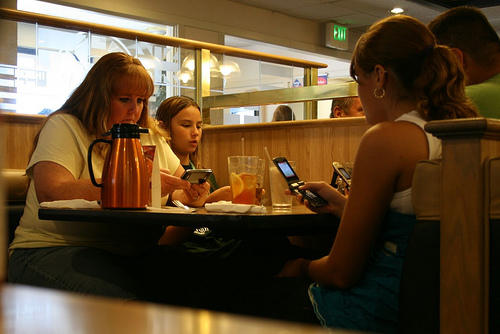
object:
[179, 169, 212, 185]
cell phone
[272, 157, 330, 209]
cell phone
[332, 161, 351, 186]
cell phone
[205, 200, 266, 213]
napkin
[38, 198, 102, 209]
napkin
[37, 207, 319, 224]
edge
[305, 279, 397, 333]
jeans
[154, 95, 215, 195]
hair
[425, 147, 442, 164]
ground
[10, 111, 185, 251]
shirt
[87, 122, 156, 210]
coffee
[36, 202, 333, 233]
table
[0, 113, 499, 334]
restaurant booth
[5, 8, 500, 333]
four people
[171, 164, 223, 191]
cell phone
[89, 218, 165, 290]
tip table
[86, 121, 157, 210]
pot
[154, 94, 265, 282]
person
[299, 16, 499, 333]
person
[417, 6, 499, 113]
person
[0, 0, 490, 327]
booth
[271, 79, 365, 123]
patrons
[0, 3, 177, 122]
window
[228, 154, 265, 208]
glass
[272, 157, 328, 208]
phone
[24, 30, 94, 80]
glass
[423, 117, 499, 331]
chair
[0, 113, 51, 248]
chair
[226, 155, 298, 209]
cups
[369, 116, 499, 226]
shoulder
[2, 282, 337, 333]
surface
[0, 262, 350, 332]
table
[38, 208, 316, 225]
table edge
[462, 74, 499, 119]
shirt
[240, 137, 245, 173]
straw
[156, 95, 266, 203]
girl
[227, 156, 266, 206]
cup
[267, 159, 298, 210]
cup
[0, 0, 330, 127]
divider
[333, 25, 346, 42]
lettering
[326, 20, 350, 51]
sign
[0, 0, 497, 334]
restaurant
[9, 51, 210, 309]
mom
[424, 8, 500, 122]
male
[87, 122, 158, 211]
carafe